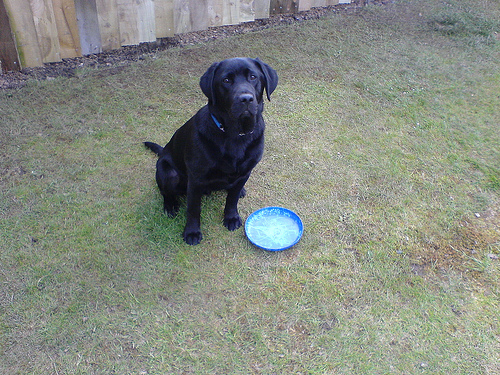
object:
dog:
[142, 57, 277, 246]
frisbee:
[241, 206, 304, 252]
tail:
[137, 139, 165, 155]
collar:
[207, 109, 254, 138]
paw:
[182, 223, 204, 245]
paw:
[222, 210, 243, 232]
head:
[197, 55, 279, 128]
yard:
[1, 0, 499, 374]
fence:
[0, 0, 355, 73]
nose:
[238, 93, 256, 104]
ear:
[197, 60, 221, 103]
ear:
[251, 56, 280, 103]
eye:
[248, 72, 258, 80]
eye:
[221, 75, 231, 83]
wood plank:
[73, 1, 103, 57]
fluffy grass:
[0, 0, 499, 375]